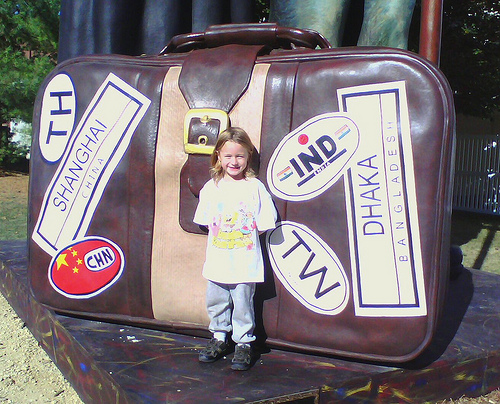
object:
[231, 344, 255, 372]
shoe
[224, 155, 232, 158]
eye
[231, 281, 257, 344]
leg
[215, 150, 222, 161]
ear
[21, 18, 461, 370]
suitcase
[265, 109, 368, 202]
sticker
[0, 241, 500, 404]
platform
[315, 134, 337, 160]
lettering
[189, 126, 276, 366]
girl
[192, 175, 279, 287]
shirt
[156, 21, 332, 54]
handle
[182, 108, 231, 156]
buckle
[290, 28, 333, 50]
strap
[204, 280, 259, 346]
pants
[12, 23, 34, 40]
leaves